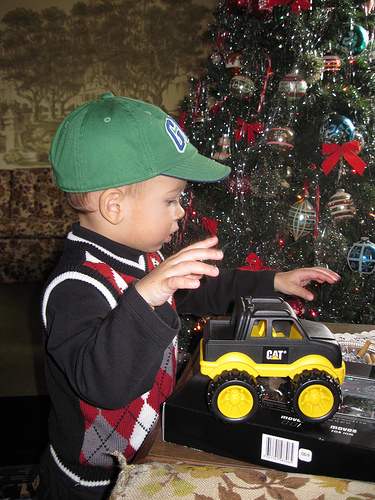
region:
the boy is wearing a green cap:
[46, 91, 229, 257]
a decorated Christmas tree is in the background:
[154, 0, 369, 322]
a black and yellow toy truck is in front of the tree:
[199, 291, 344, 426]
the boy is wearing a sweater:
[37, 225, 273, 484]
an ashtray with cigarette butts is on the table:
[338, 335, 372, 360]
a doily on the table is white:
[333, 320, 372, 346]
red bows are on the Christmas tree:
[171, 98, 370, 276]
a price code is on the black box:
[165, 379, 368, 480]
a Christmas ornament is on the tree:
[285, 186, 315, 239]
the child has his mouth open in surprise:
[50, 161, 189, 254]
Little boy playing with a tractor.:
[50, 98, 262, 492]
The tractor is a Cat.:
[228, 319, 303, 374]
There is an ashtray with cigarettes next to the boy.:
[328, 320, 373, 375]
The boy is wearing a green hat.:
[47, 94, 219, 194]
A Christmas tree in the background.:
[207, 10, 372, 228]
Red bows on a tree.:
[301, 124, 369, 182]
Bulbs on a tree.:
[253, 61, 322, 175]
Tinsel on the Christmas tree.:
[217, 11, 373, 252]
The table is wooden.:
[315, 302, 373, 387]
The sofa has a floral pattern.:
[128, 465, 373, 499]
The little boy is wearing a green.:
[46, 84, 232, 203]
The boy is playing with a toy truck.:
[185, 282, 350, 433]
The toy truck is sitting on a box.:
[204, 295, 354, 426]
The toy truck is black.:
[195, 294, 343, 426]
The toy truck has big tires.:
[196, 293, 345, 431]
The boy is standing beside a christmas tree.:
[164, 2, 373, 383]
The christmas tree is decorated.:
[156, 0, 374, 376]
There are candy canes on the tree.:
[247, 46, 279, 121]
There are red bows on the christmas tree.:
[314, 136, 369, 178]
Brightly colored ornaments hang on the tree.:
[222, 67, 260, 102]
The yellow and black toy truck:
[197, 294, 349, 425]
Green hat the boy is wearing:
[45, 85, 236, 195]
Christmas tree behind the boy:
[161, 0, 374, 335]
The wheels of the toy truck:
[213, 365, 344, 426]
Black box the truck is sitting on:
[156, 362, 374, 482]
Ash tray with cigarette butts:
[332, 335, 374, 365]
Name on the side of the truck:
[261, 341, 290, 361]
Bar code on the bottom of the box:
[259, 430, 307, 465]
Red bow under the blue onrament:
[316, 138, 368, 175]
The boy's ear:
[96, 185, 131, 227]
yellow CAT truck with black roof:
[194, 287, 354, 426]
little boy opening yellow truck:
[29, 86, 374, 497]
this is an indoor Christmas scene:
[2, 25, 371, 494]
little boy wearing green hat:
[30, 85, 234, 487]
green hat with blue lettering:
[47, 86, 237, 193]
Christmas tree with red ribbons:
[159, 2, 373, 329]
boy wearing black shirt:
[15, 86, 341, 494]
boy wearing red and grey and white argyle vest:
[31, 87, 343, 496]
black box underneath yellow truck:
[164, 292, 374, 483]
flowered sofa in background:
[4, 157, 104, 283]